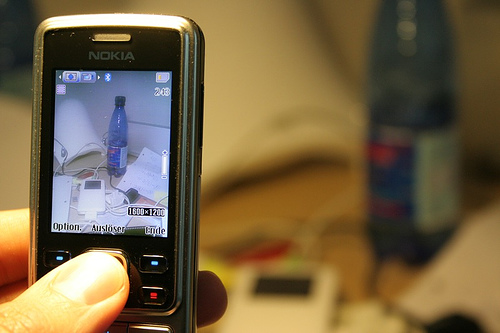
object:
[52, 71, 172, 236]
screen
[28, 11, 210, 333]
phone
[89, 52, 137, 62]
brand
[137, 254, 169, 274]
button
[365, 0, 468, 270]
bottle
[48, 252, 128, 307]
finger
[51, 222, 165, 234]
option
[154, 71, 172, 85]
life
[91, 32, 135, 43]
speaker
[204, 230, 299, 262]
book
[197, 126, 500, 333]
bed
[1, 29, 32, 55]
pillow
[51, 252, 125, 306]
nail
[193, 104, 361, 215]
counter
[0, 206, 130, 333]
person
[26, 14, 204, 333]
device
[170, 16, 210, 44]
edge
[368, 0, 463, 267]
part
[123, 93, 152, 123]
part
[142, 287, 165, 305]
part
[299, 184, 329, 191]
part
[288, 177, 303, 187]
table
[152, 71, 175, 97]
part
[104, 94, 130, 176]
gadget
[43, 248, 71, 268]
key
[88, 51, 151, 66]
compan